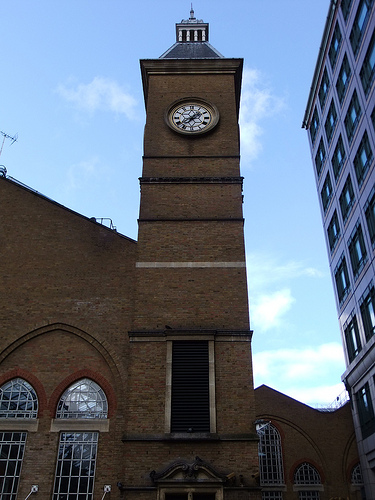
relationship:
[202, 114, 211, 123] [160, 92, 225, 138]
numeral on a clock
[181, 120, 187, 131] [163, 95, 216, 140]
numeral on a clock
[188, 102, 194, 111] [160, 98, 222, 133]
numeral on clock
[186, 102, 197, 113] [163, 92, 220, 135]
numeral on clock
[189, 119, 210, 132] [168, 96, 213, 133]
roman numeral on clock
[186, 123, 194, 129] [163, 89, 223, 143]
roman numeral on clock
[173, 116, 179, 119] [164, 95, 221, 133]
roman numeral on clock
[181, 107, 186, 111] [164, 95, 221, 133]
roman numeral on clock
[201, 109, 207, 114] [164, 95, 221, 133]
roman numeral on clock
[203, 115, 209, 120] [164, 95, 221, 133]
numeral on clock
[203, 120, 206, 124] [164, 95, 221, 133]
roman numeral on clock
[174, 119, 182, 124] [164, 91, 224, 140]
numeral on clock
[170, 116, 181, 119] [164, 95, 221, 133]
roman numeral on clock